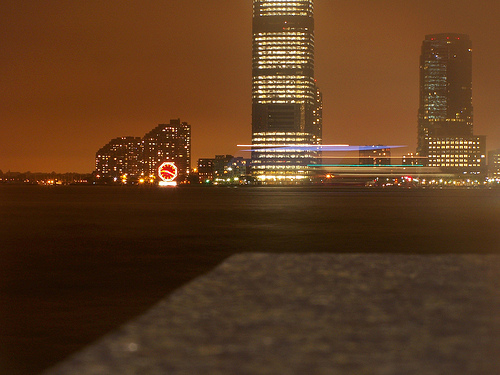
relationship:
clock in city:
[151, 157, 180, 190] [2, 5, 499, 186]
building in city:
[249, 4, 318, 189] [2, 5, 499, 186]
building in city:
[414, 35, 482, 169] [2, 5, 499, 186]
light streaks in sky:
[235, 133, 446, 179] [0, 1, 499, 169]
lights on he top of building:
[426, 32, 465, 43] [414, 35, 482, 169]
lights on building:
[426, 32, 465, 43] [414, 35, 482, 169]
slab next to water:
[44, 249, 500, 373] [2, 185, 498, 372]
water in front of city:
[2, 185, 498, 372] [2, 5, 499, 186]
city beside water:
[2, 5, 499, 186] [2, 185, 498, 372]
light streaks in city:
[235, 133, 446, 179] [2, 5, 499, 186]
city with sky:
[2, 5, 499, 186] [0, 1, 499, 169]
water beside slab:
[2, 185, 498, 372] [44, 249, 500, 373]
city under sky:
[2, 5, 499, 186] [0, 1, 499, 169]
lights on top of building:
[426, 32, 465, 43] [414, 35, 482, 169]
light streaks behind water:
[235, 133, 446, 179] [2, 185, 498, 372]